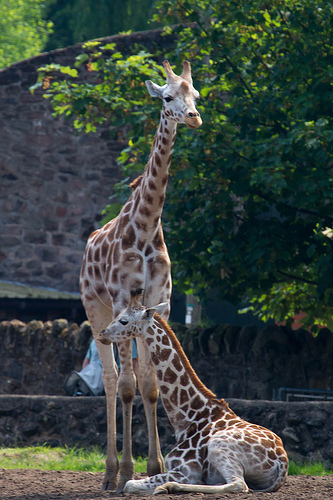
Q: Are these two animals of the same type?
A: Yes, all the animals are giraffes.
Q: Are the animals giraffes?
A: Yes, all the animals are giraffes.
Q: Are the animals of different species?
A: No, all the animals are giraffes.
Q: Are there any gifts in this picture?
A: No, there are no gifts.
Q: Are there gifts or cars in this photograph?
A: No, there are no gifts or cars.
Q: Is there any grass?
A: Yes, there is grass.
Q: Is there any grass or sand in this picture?
A: Yes, there is grass.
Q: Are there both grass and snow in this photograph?
A: No, there is grass but no snow.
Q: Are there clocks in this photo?
A: No, there are no clocks.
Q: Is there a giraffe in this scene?
A: Yes, there is a giraffe.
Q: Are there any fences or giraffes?
A: Yes, there is a giraffe.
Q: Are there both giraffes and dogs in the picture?
A: No, there is a giraffe but no dogs.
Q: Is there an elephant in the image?
A: No, there are no elephants.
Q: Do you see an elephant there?
A: No, there are no elephants.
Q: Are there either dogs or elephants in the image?
A: No, there are no elephants or dogs.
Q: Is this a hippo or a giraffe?
A: This is a giraffe.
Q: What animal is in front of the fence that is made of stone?
A: The giraffe is in front of the fence.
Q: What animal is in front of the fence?
A: The giraffe is in front of the fence.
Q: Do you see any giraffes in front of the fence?
A: Yes, there is a giraffe in front of the fence.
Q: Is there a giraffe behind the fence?
A: No, the giraffe is in front of the fence.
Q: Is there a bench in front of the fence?
A: No, there is a giraffe in front of the fence.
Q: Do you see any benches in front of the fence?
A: No, there is a giraffe in front of the fence.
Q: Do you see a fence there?
A: Yes, there is a fence.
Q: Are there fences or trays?
A: Yes, there is a fence.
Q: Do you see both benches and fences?
A: No, there is a fence but no benches.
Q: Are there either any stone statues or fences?
A: Yes, there is a stone fence.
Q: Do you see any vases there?
A: No, there are no vases.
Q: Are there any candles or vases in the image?
A: No, there are no vases or candles.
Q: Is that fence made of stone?
A: Yes, the fence is made of stone.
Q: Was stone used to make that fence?
A: Yes, the fence is made of stone.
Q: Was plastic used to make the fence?
A: No, the fence is made of stone.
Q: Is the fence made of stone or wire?
A: The fence is made of stone.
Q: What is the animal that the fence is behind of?
A: The animal is a giraffe.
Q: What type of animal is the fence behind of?
A: The fence is behind the giraffe.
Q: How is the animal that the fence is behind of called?
A: The animal is a giraffe.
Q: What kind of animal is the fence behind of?
A: The fence is behind the giraffe.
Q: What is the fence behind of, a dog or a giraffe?
A: The fence is behind a giraffe.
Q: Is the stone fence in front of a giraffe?
A: No, the fence is behind a giraffe.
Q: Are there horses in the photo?
A: No, there are no horses.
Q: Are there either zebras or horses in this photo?
A: No, there are no horses or zebras.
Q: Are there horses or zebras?
A: No, there are no horses or zebras.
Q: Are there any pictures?
A: No, there are no pictures.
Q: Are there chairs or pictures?
A: No, there are no pictures or chairs.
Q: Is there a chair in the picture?
A: No, there are no chairs.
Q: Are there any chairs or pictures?
A: No, there are no chairs or pictures.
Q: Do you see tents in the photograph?
A: No, there are no tents.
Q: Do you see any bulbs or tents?
A: No, there are no tents or bulbs.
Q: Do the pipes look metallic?
A: Yes, the pipes are metallic.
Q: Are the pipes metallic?
A: Yes, the pipes are metallic.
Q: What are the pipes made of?
A: The pipes are made of metal.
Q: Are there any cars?
A: No, there are no cars.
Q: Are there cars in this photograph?
A: No, there are no cars.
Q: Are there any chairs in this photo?
A: No, there are no chairs.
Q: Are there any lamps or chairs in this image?
A: No, there are no chairs or lamps.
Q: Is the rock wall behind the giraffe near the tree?
A: Yes, the wall is behind the giraffe.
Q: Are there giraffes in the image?
A: Yes, there is a giraffe.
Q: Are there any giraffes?
A: Yes, there is a giraffe.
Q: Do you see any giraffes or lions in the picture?
A: Yes, there is a giraffe.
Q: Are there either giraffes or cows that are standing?
A: Yes, the giraffe is standing.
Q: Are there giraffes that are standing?
A: Yes, there is a giraffe that is standing.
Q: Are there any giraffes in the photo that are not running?
A: Yes, there is a giraffe that is standing.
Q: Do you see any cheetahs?
A: No, there are no cheetahs.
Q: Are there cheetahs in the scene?
A: No, there are no cheetahs.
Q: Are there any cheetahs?
A: No, there are no cheetahs.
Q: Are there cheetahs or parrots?
A: No, there are no cheetahs or parrots.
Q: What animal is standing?
A: The animal is a giraffe.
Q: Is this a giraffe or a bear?
A: This is a giraffe.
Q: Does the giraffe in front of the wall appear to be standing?
A: Yes, the giraffe is standing.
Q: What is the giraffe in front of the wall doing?
A: The giraffe is standing.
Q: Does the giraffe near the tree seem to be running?
A: No, the giraffe is standing.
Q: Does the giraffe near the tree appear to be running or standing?
A: The giraffe is standing.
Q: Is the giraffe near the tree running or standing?
A: The giraffe is standing.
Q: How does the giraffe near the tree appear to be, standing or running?
A: The giraffe is standing.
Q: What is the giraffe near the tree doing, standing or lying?
A: The giraffe is standing.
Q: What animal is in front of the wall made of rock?
A: The giraffe is in front of the wall.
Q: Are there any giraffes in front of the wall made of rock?
A: Yes, there is a giraffe in front of the wall.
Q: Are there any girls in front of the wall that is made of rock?
A: No, there is a giraffe in front of the wall.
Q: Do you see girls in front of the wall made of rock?
A: No, there is a giraffe in front of the wall.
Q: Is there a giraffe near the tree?
A: Yes, there is a giraffe near the tree.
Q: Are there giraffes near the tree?
A: Yes, there is a giraffe near the tree.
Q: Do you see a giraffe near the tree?
A: Yes, there is a giraffe near the tree.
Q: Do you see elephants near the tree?
A: No, there is a giraffe near the tree.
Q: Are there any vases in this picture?
A: No, there are no vases.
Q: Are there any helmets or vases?
A: No, there are no vases or helmets.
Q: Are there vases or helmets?
A: No, there are no vases or helmets.